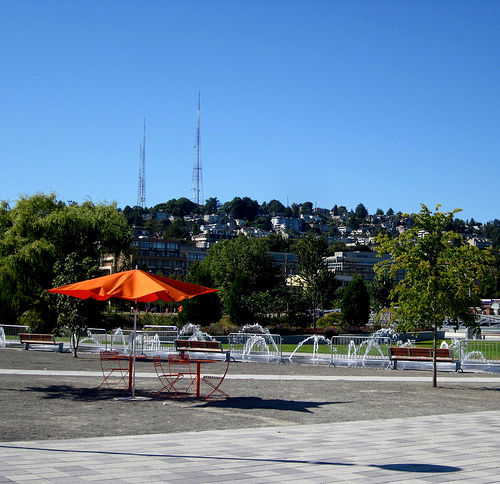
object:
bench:
[387, 345, 464, 373]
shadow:
[190, 396, 354, 414]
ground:
[375, 421, 498, 481]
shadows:
[0, 383, 122, 402]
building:
[337, 248, 374, 277]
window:
[153, 241, 162, 249]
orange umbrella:
[46, 264, 219, 402]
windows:
[167, 241, 182, 251]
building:
[122, 235, 184, 266]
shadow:
[2, 444, 462, 474]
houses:
[121, 203, 496, 251]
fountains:
[289, 334, 339, 365]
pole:
[132, 302, 137, 399]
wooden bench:
[18, 332, 65, 353]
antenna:
[190, 89, 205, 210]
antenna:
[137, 115, 148, 209]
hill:
[0, 197, 499, 346]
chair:
[98, 348, 132, 392]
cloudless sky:
[0, 0, 498, 226]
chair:
[152, 354, 183, 399]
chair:
[200, 351, 231, 402]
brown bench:
[173, 338, 231, 363]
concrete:
[235, 372, 267, 379]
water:
[237, 323, 265, 333]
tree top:
[376, 204, 497, 331]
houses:
[347, 210, 393, 250]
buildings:
[270, 215, 300, 234]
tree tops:
[199, 231, 284, 286]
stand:
[113, 350, 151, 402]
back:
[404, 348, 429, 360]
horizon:
[23, 182, 462, 230]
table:
[117, 355, 214, 398]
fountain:
[347, 326, 414, 370]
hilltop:
[81, 183, 451, 313]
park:
[0, 290, 499, 482]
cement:
[360, 418, 485, 478]